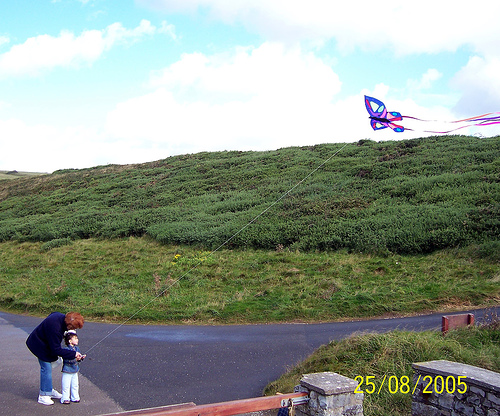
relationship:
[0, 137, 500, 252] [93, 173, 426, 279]
green field covered in grass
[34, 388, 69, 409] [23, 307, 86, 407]
feet of woman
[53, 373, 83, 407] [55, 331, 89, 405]
pants on child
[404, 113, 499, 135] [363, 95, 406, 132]
tail of kite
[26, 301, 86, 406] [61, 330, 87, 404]
mother teaching child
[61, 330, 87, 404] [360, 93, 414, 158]
child flying kite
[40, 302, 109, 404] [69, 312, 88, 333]
child has head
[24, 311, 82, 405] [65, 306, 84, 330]
mother with hair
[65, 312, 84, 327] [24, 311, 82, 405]
head of mother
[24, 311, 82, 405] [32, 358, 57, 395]
mother wearing blue jeans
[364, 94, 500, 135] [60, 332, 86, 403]
kite being flown by a child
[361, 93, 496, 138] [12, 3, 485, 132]
kite in air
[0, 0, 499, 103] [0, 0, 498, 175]
fluffy clouds in sky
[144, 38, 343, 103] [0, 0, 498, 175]
fluffy clouds in sky